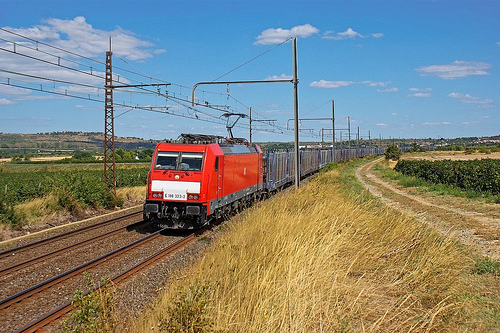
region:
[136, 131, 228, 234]
front part of the train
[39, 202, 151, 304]
two long rail way tracks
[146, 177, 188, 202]
number of the train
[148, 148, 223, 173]
front window of the train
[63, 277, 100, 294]
stones inside the track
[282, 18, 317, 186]
a long electric poll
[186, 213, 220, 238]
wheel of the train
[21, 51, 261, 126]
a small thing electrical wires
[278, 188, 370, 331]
a beautiful view of grass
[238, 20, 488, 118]
small white clouds in sky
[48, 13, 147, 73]
white clouds clear sky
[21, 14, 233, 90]
white clouds clear sky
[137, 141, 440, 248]
A ling freight train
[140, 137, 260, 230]
A red train engine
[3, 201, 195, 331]
a set of railroad tracks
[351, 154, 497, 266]
A dirt road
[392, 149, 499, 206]
A group of bushes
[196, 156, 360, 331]
some tall grass next to the tracks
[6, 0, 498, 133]
A clear blue sky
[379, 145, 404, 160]
A small tree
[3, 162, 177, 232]
A grassy field next to the track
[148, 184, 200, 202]
headlights on the train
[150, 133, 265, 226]
the red front car of a train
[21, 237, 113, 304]
two sets of rusted train tracks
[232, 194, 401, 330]
high brown grass by the tracks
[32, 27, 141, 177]
a rusted old power pole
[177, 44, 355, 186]
large curved poles over the train tracks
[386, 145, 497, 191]
tall green growth in a field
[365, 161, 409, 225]
a tire beaten path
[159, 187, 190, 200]
black text numbers on the front of a train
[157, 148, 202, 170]
the front windshield of the train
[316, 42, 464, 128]
sparse tiny white clouds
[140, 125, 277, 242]
the train on the tracks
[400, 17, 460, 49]
the sky is blue and clear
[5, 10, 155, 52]
clouds in the sky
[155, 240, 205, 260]
gravel beside the tracks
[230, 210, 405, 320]
the grass beside the tracks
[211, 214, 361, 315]
the grass is long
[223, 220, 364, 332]
the grass is dry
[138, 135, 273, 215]
the train is red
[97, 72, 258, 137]
the power cables above the train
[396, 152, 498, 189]
the green hedges